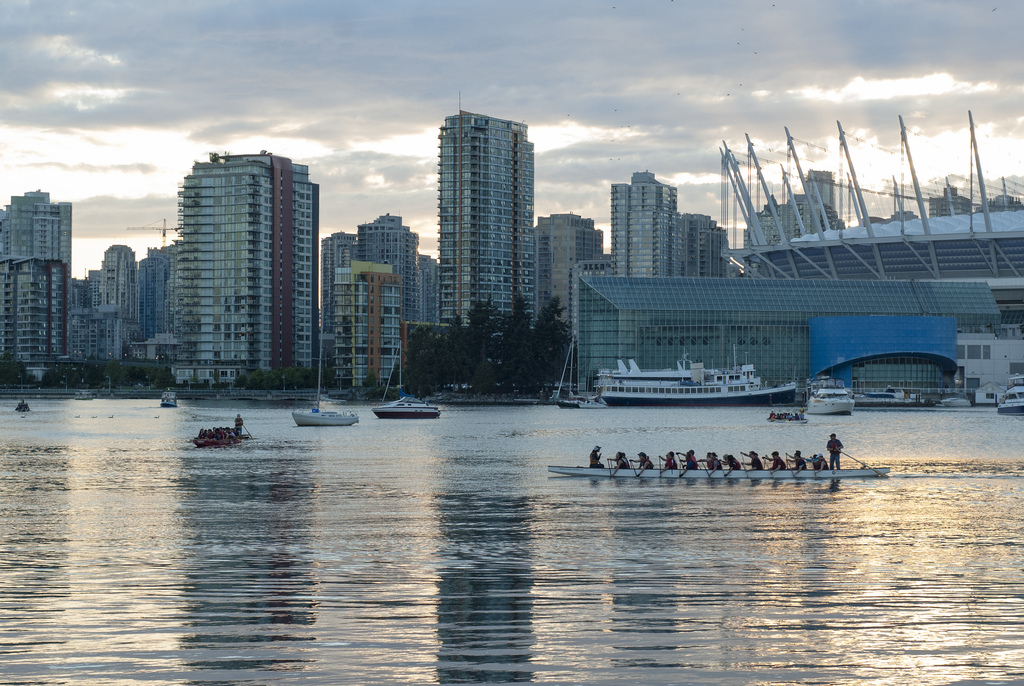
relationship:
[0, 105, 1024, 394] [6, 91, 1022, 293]
building on skyline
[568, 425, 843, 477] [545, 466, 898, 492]
people sitting on canoe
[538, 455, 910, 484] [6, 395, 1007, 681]
canoe on lake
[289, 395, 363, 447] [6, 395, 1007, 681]
boat in lake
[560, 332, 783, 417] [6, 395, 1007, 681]
boat in lake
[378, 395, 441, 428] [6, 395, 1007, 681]
boat in lake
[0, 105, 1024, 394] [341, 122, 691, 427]
building in middle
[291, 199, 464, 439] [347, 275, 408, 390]
building with windows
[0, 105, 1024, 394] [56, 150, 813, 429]
building in background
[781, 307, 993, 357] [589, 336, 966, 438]
wall behind boats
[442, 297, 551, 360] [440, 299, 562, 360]
tree with leaves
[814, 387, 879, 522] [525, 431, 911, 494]
man in canoe